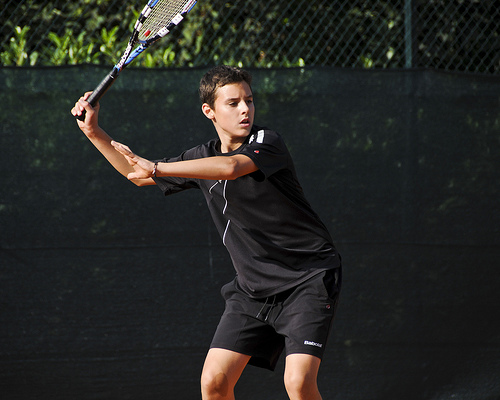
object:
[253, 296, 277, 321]
string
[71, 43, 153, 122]
racket's handle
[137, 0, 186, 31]
strings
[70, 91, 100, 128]
hand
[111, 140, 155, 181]
hand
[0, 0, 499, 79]
chain link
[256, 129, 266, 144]
stripe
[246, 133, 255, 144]
stripe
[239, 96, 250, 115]
nose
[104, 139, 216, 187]
arm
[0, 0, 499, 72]
trees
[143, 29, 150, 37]
sticker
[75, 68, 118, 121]
handle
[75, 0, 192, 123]
racket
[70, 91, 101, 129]
boy's hand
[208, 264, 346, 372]
shorts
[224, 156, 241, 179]
elbow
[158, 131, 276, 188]
arm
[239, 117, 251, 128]
mouth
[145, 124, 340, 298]
shirt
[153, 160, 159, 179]
bracelet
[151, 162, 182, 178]
boy's wrist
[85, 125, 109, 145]
boy's wrist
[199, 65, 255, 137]
head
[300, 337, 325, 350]
logo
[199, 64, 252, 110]
hair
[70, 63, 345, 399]
boy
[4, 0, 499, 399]
fence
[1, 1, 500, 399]
tennis court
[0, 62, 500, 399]
fabric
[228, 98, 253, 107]
eye